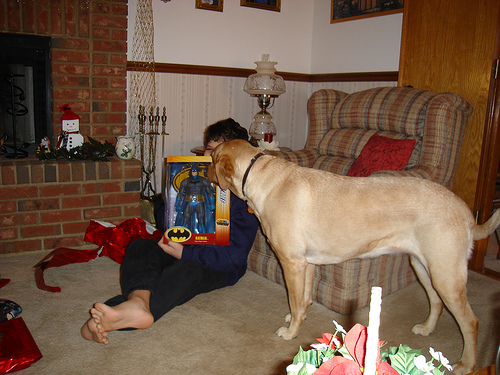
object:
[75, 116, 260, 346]
boy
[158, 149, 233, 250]
present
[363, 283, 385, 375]
handle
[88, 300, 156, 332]
foot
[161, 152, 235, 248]
batman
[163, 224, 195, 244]
logo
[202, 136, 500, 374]
dog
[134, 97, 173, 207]
tools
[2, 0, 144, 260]
fireplace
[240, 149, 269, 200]
collar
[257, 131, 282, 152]
candle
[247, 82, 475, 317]
chair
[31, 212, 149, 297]
paper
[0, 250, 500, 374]
floor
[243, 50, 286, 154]
lamp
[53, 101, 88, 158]
snowman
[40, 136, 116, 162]
branch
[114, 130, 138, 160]
vase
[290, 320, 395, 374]
flower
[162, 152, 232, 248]
box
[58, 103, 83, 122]
hat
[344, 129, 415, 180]
pillow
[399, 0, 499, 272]
door